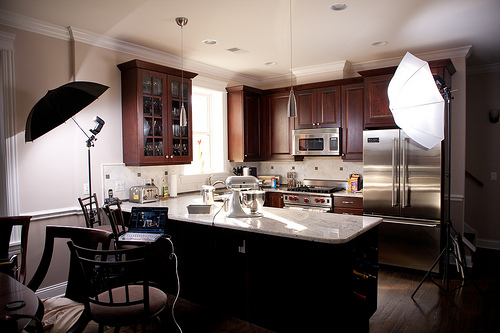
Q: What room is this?
A: Kitchen.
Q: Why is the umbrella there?
A: Reflecting light.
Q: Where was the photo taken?
A: In a kitchen.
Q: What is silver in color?
A: The fridge.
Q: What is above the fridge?
A: Cabinets.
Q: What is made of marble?
A: Countertop.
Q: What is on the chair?
A: Laptop.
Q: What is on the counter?
A: A mixer.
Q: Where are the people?
A: No people.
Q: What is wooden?
A: The floor.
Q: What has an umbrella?
A: The light.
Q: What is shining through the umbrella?
A: Light.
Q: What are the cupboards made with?
A: Wood.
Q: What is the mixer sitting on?
A: The counter.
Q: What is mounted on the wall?
A: A cabinet.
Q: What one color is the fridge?
A: Silver.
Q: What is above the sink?
A: A window.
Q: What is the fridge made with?
A: Stainless steel.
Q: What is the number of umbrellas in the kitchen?
A: Two.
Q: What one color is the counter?
A: White.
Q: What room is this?
A: The kitchen.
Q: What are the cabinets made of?
A: Wood.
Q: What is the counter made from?
A: Marble.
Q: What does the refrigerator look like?
A: Stainless steel.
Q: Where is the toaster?
A: On the counter.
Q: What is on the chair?
A: A laptop.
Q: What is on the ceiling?
A: Lights.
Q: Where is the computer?
A: Stool.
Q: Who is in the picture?
A: No one.